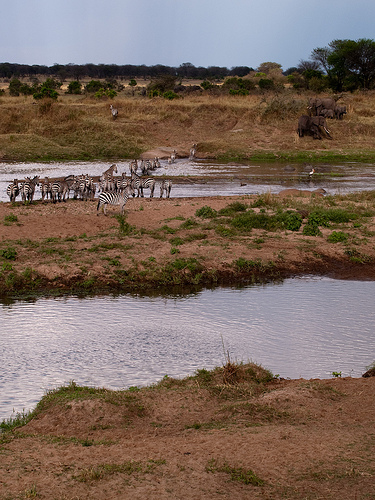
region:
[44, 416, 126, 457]
white clouds in blue sky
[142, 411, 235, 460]
white clouds in blue sky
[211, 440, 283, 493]
white clouds in blue sky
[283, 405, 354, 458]
white clouds in blue sky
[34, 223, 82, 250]
white clouds in blue sky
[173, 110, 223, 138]
white clouds in blue sky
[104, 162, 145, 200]
zebra crossing river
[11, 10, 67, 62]
white clouds against blue sky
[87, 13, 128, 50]
white clouds against blue sky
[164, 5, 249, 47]
white clouds against blue sky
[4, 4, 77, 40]
white clouds in blue sky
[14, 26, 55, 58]
white clouds in blue sky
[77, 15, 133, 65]
white clouds in blue sky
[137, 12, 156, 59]
white clouds in blue sky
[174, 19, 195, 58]
white clouds in blue sky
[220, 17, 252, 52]
white clouds in blue sky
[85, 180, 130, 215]
black and white zebra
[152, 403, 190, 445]
gren and brown grass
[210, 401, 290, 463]
gren and brown grass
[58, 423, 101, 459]
gren and brown grass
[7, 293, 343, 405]
body of water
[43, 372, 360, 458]
edge of piece of land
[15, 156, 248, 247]
herd of zebras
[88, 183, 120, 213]
black and white stripes on zebra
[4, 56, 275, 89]
trees on the horizon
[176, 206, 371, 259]
green shrubs on dirt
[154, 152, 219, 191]
zebras in the water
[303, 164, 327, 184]
white bird with yellow beak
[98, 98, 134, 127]
zebra coming down incline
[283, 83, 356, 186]
elephants near the water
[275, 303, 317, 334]
the water has ripples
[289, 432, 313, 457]
the dirt is tan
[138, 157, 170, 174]
the zebras are in the water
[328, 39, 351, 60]
the tree has leaves on it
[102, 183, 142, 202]
the zebra is black and white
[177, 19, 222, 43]
the sky is hazy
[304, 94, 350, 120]
the elephants are gathered together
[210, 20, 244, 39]
the sky is light blue in color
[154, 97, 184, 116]
the grass is dead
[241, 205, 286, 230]
the grass is green in color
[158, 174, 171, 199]
a standing black and white zebra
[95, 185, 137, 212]
a standing black and white zebra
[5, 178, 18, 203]
a standing black and white zebra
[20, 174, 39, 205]
a standing black and white zebra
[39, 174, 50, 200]
a standing black and white zebra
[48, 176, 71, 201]
a standing black and white zebra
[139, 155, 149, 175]
a standing black and white zebra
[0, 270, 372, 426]
a river of water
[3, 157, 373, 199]
a river of water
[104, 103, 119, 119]
a zebra on hill